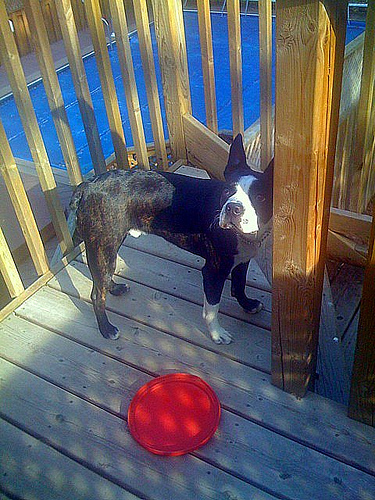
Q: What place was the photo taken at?
A: It was taken at the swimming pool.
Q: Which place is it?
A: It is a swimming pool.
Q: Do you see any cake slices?
A: No, there are no cake slices.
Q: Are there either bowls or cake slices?
A: No, there are no cake slices or bowls.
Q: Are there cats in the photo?
A: No, there are no cats.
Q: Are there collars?
A: Yes, there is a collar.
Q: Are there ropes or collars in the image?
A: Yes, there is a collar.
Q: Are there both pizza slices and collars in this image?
A: No, there is a collar but no pizza slices.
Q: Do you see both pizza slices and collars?
A: No, there is a collar but no pizza slices.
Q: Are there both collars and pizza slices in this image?
A: No, there is a collar but no pizza slices.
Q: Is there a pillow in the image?
A: No, there are no pillows.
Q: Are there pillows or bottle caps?
A: No, there are no pillows or bottle caps.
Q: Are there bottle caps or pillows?
A: No, there are no pillows or bottle caps.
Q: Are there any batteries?
A: No, there are no batteries.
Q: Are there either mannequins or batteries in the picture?
A: No, there are no batteries or mannequins.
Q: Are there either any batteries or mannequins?
A: No, there are no batteries or mannequins.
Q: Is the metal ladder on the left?
A: Yes, the ladder is on the left of the image.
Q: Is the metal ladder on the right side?
A: No, the ladder is on the left of the image.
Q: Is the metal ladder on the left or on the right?
A: The ladder is on the left of the image.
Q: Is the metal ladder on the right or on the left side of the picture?
A: The ladder is on the left of the image.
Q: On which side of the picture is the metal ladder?
A: The ladder is on the left of the image.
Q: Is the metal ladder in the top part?
A: Yes, the ladder is in the top of the image.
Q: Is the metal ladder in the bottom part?
A: No, the ladder is in the top of the image.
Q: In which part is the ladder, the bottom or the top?
A: The ladder is in the top of the image.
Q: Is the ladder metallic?
A: Yes, the ladder is metallic.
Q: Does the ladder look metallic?
A: Yes, the ladder is metallic.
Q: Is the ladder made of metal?
A: Yes, the ladder is made of metal.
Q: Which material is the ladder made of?
A: The ladder is made of metal.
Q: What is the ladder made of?
A: The ladder is made of metal.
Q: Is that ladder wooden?
A: No, the ladder is metallic.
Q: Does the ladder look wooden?
A: No, the ladder is metallic.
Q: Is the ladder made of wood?
A: No, the ladder is made of metal.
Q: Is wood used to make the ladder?
A: No, the ladder is made of metal.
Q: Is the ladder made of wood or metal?
A: The ladder is made of metal.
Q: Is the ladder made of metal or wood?
A: The ladder is made of metal.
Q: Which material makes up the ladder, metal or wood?
A: The ladder is made of metal.